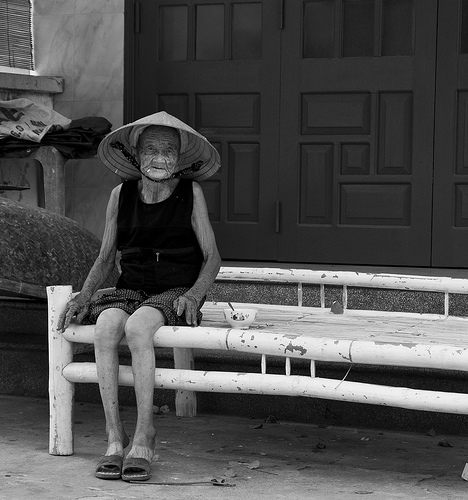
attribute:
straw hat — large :
[99, 107, 220, 184]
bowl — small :
[223, 306, 257, 331]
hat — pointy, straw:
[99, 109, 222, 183]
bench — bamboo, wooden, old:
[30, 263, 467, 459]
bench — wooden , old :
[37, 262, 466, 481]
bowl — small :
[220, 304, 258, 326]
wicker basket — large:
[0, 193, 116, 310]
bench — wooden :
[254, 260, 467, 416]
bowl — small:
[220, 302, 258, 327]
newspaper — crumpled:
[8, 80, 68, 165]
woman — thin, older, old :
[55, 104, 231, 483]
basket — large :
[57, 274, 133, 327]